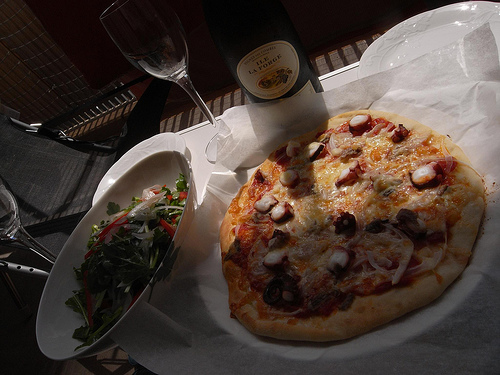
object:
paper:
[112, 25, 497, 374]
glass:
[100, 1, 242, 161]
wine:
[203, 0, 324, 104]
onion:
[408, 160, 445, 191]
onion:
[266, 227, 293, 251]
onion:
[345, 111, 374, 137]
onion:
[260, 248, 292, 270]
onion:
[324, 244, 356, 280]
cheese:
[248, 130, 452, 297]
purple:
[389, 122, 413, 144]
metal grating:
[32, 76, 140, 144]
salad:
[56, 168, 194, 360]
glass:
[1, 180, 63, 285]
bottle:
[203, 1, 326, 111]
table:
[36, 27, 497, 362]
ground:
[332, 117, 356, 144]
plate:
[32, 148, 198, 360]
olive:
[253, 273, 307, 310]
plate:
[194, 103, 499, 363]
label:
[233, 39, 300, 102]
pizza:
[217, 108, 487, 343]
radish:
[334, 160, 367, 190]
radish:
[327, 208, 357, 237]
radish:
[268, 200, 293, 223]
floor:
[25, 15, 479, 108]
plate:
[357, 0, 498, 80]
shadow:
[157, 13, 378, 118]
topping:
[388, 205, 434, 240]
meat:
[250, 190, 280, 214]